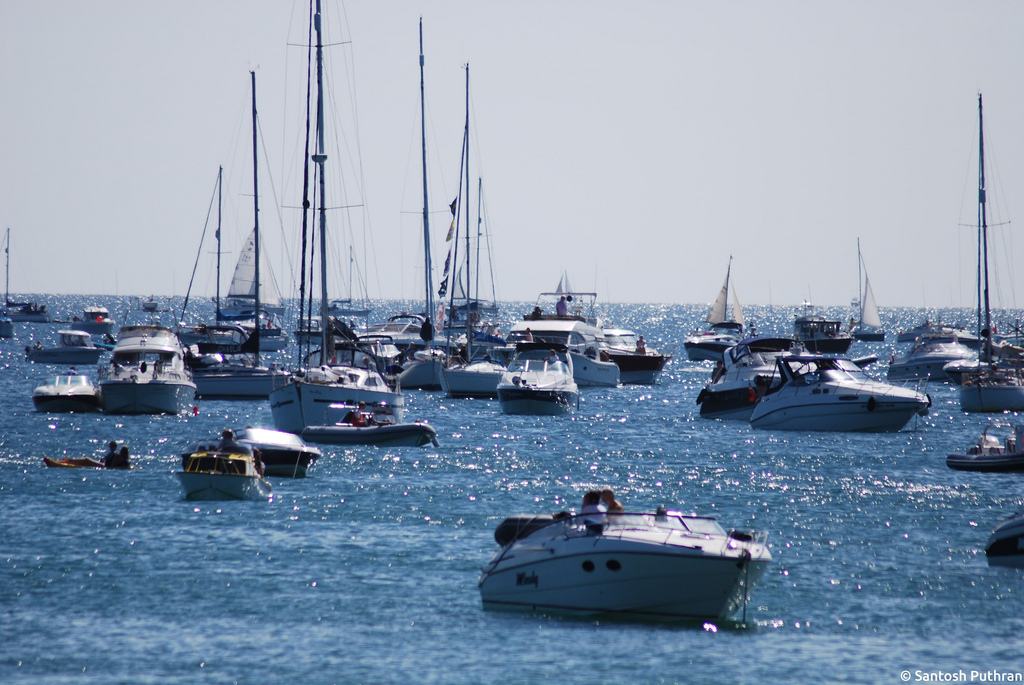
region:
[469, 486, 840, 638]
Cabin cruiser riding on the water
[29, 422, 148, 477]
People in the kayak on the water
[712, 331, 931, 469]
Cabin cruiser near many other boats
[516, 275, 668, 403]
Person standing outside his boat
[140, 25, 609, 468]
Several sail boats on the water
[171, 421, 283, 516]
Small boat near the other larger boats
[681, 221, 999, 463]
Sailboats near the larger other boats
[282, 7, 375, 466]
Large mast on the sailboat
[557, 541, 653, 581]
Window on the side if the cabin crusier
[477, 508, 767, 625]
boat docked in water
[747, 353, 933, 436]
boat docked in water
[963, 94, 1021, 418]
boat docked in water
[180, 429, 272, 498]
boat docked in water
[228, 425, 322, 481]
boat docked in water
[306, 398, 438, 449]
boat docked in water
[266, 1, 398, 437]
boat docked in water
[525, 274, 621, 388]
boat docked in water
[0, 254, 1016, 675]
white boats in water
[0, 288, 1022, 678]
water that looks blue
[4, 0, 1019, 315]
sky looks gray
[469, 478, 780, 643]
boats has purple light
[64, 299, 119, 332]
boat with red light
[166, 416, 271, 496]
person standing in boat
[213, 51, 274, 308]
boat with white flag pole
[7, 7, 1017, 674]
boats sailing in water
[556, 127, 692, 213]
a view of sky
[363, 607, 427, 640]
a view of water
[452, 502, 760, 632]
a view of boat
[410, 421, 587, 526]
marks in the waters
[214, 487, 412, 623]
riddles in the water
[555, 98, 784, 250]
a view of clouds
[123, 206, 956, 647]
a group of boats in water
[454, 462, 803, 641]
the boat is white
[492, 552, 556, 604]
writing on the boat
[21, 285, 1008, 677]
the water is blue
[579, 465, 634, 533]
people on a boat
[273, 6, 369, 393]
a set of poles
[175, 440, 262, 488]
yellow trim on the boat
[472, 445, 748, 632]
boat docked in blue water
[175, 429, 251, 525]
boat docked in blue water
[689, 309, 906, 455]
boat docked in blue water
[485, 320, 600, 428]
boat docked in blue water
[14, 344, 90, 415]
boat docked in blue water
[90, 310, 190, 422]
boat docked in blue water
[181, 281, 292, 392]
boat docked in blue water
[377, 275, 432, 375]
boat docked in blue water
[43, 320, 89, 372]
boat docked in blue water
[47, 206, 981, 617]
boats in the water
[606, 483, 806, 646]
front of the boat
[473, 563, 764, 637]
bottom of the boat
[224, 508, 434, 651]
waves in the water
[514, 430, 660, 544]
people on the boat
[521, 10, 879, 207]
sky above the water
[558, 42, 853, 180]
gray sky above the ocean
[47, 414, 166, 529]
people in the water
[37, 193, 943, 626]
many boats in the ocean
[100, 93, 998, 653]
this is a marina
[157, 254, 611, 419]
the boats are parked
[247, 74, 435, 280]
the masts are tall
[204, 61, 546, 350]
the masts are black